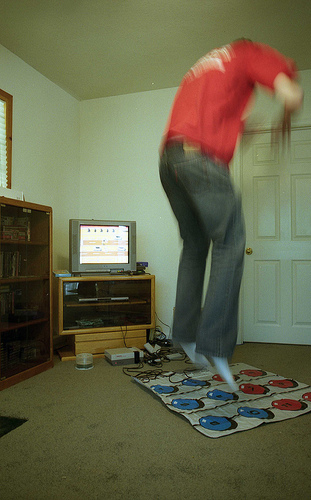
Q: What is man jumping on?
A: Blue circles on pad.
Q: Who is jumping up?
A: The man.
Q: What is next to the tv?
A: Bookcase.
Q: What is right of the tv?
A: The door.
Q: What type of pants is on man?
A: Blue jeans.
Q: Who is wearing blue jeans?
A: The man.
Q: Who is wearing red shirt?
A: Man jumping.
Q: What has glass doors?
A: Wood media center.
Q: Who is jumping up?
A: Man in red shirt.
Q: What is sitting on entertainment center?
A: Tv.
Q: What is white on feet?
A: Socks.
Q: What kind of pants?
A: Jeans.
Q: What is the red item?
A: Man's shirt.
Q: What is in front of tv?
A: The man.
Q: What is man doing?
A: Jumping.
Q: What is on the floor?
A: Rug.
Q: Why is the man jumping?
A: It's a part of the game.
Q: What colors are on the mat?
A: Red and blue.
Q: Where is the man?
A: In a house.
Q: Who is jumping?
A: A man.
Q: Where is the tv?
A: On a stand.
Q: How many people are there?
A: 1.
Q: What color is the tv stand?
A: Brown.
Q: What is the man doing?
A: Jumping.